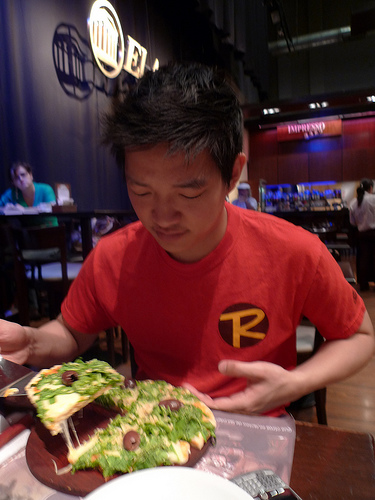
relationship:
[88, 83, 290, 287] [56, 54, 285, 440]
head of person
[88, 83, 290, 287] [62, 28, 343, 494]
head of man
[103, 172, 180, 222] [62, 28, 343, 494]
eye of man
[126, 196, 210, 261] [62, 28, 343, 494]
nsoe of man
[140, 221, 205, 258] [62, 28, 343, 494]
mouth of man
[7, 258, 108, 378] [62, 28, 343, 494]
hand of man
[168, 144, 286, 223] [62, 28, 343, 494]
ear of man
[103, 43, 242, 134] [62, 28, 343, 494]
hair of man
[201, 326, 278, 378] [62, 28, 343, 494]
thumb of man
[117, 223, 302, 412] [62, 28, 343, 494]
shirt on man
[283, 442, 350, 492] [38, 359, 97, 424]
table with food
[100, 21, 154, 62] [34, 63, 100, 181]
letter on wall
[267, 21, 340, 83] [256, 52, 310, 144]
light on ceiling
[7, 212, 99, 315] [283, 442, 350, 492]
chair at table